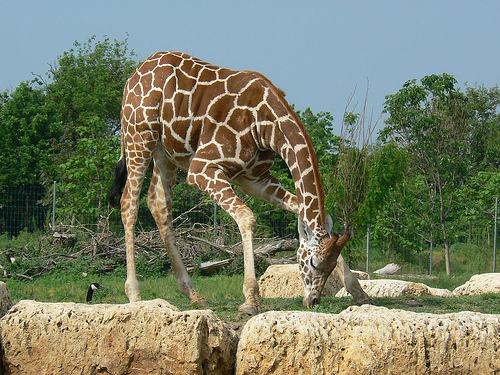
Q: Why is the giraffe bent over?
A: Eating the grass.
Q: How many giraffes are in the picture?
A: 1.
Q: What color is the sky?
A: Blue.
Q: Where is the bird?
A: Beside the giraffe.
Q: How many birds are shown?
A: 1.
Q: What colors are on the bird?
A: Black with white.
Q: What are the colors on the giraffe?
A: Brown and white.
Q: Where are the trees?
A: Behind the animals.